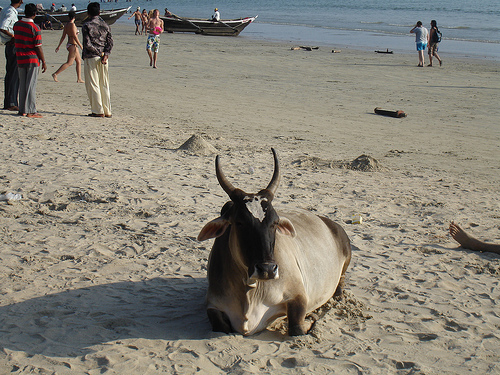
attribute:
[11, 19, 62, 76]
shirt — striped 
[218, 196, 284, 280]
cow face — black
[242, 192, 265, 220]
marking — white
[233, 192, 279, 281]
face — black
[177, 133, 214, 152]
sand — pile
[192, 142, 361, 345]
goat — lying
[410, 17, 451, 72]
people — walking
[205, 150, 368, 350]
cow — horned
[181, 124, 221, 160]
shape — pyramid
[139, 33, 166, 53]
trunks — swim 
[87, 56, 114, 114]
pants — white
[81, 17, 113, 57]
shirt — dark 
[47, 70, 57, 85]
foot — person's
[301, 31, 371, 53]
edge — water's